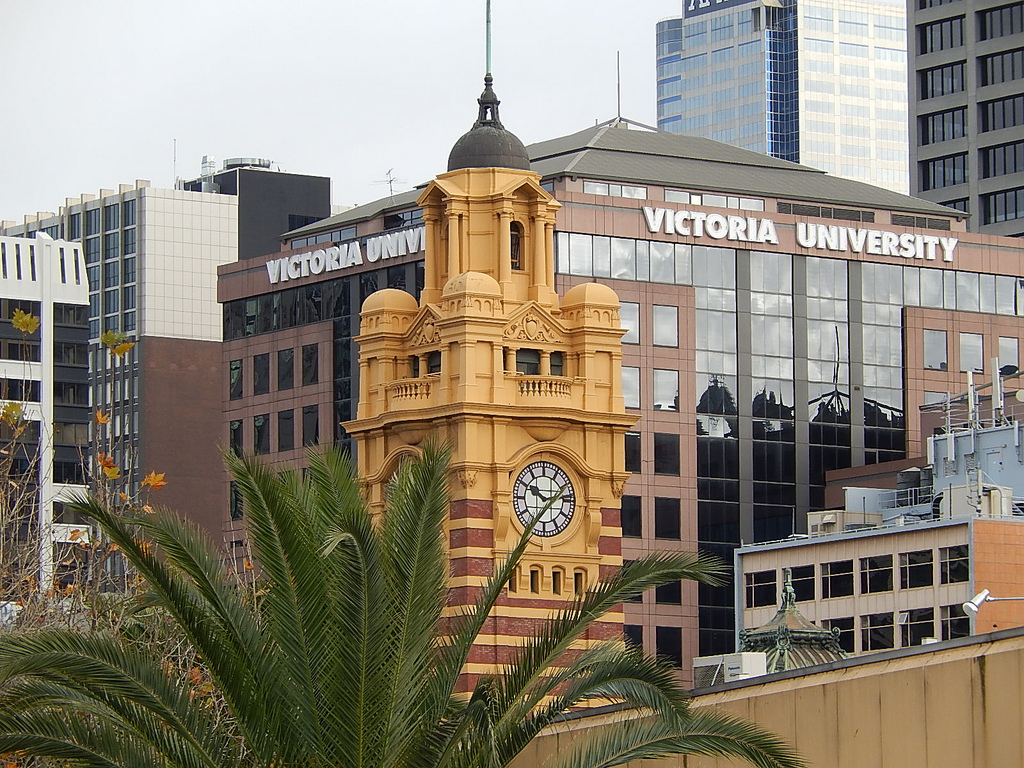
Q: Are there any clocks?
A: Yes, there is a clock.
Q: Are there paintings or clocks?
A: Yes, there is a clock.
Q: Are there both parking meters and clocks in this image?
A: No, there is a clock but no parking meters.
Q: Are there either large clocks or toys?
A: Yes, there is a large clock.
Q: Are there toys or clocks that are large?
A: Yes, the clock is large.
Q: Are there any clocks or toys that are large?
A: Yes, the clock is large.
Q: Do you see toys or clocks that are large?
A: Yes, the clock is large.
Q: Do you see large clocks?
A: Yes, there is a large clock.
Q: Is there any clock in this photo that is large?
A: Yes, there is a clock that is large.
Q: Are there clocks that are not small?
A: Yes, there is a large clock.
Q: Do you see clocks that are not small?
A: Yes, there is a large clock.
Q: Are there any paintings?
A: No, there are no paintings.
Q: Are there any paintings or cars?
A: No, there are no paintings or cars.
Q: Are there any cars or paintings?
A: No, there are no paintings or cars.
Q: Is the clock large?
A: Yes, the clock is large.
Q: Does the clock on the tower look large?
A: Yes, the clock is large.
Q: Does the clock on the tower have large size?
A: Yes, the clock is large.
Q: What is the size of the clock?
A: The clock is large.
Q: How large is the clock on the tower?
A: The clock is large.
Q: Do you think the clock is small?
A: No, the clock is large.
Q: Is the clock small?
A: No, the clock is large.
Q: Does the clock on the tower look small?
A: No, the clock is large.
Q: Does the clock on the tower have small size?
A: No, the clock is large.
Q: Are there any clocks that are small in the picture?
A: No, there is a clock but it is large.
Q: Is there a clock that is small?
A: No, there is a clock but it is large.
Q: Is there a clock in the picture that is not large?
A: No, there is a clock but it is large.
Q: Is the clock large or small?
A: The clock is large.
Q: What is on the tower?
A: The clock is on the tower.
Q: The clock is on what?
A: The clock is on the tower.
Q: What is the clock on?
A: The clock is on the tower.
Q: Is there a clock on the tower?
A: Yes, there is a clock on the tower.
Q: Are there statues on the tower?
A: No, there is a clock on the tower.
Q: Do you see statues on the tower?
A: No, there is a clock on the tower.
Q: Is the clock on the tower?
A: Yes, the clock is on the tower.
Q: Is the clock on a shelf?
A: No, the clock is on the tower.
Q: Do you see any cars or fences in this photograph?
A: No, there are no cars or fences.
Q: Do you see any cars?
A: No, there are no cars.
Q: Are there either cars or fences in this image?
A: No, there are no cars or fences.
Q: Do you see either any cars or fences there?
A: No, there are no cars or fences.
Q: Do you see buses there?
A: No, there are no buses.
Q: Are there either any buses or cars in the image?
A: No, there are no buses or cars.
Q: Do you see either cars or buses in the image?
A: No, there are no buses or cars.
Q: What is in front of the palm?
A: The building is in front of the palm.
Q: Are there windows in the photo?
A: Yes, there is a window.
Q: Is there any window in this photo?
A: Yes, there is a window.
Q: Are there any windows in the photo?
A: Yes, there is a window.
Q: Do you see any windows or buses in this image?
A: Yes, there is a window.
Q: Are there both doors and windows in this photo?
A: No, there is a window but no doors.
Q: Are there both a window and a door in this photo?
A: No, there is a window but no doors.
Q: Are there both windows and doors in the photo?
A: No, there is a window but no doors.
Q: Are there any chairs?
A: No, there are no chairs.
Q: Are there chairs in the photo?
A: No, there are no chairs.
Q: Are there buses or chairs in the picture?
A: No, there are no chairs or buses.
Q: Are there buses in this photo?
A: No, there are no buses.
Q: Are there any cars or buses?
A: No, there are no buses or cars.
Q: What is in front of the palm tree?
A: The building is in front of the palm tree.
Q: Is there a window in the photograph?
A: Yes, there is a window.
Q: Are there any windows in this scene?
A: Yes, there is a window.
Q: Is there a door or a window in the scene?
A: Yes, there is a window.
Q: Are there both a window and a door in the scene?
A: No, there is a window but no doors.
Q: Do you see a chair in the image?
A: No, there are no chairs.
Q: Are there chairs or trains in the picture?
A: No, there are no chairs or trains.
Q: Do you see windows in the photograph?
A: Yes, there is a window.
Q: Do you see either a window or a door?
A: Yes, there is a window.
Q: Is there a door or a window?
A: Yes, there is a window.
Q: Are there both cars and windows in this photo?
A: No, there is a window but no cars.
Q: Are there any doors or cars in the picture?
A: No, there are no cars or doors.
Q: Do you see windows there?
A: Yes, there is a window.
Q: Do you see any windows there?
A: Yes, there is a window.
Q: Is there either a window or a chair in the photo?
A: Yes, there is a window.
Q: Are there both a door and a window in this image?
A: No, there is a window but no doors.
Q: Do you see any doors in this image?
A: No, there are no doors.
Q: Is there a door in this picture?
A: No, there are no doors.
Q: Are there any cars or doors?
A: No, there are no doors or cars.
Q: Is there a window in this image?
A: Yes, there is a window.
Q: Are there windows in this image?
A: Yes, there is a window.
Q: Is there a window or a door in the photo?
A: Yes, there is a window.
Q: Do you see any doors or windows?
A: Yes, there is a window.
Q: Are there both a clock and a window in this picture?
A: Yes, there are both a window and a clock.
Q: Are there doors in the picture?
A: No, there are no doors.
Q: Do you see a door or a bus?
A: No, there are no doors or buses.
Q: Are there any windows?
A: Yes, there is a window.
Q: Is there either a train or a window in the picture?
A: Yes, there is a window.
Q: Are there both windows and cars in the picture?
A: No, there is a window but no cars.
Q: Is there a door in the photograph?
A: No, there are no doors.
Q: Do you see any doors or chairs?
A: No, there are no doors or chairs.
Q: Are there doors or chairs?
A: No, there are no doors or chairs.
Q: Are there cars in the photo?
A: No, there are no cars.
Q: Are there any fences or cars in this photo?
A: No, there are no cars or fences.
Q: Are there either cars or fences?
A: No, there are no cars or fences.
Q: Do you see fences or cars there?
A: No, there are no cars or fences.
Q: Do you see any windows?
A: Yes, there is a window.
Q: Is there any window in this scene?
A: Yes, there is a window.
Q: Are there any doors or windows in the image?
A: Yes, there is a window.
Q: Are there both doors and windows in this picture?
A: No, there is a window but no doors.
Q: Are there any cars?
A: No, there are no cars.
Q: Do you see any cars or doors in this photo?
A: No, there are no cars or doors.